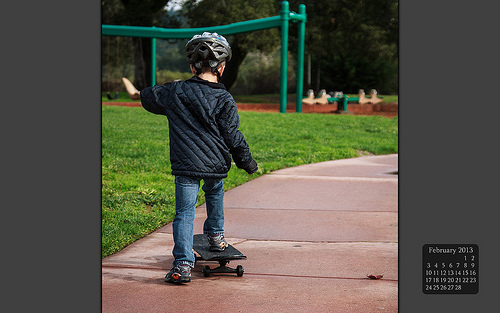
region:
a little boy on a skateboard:
[96, 18, 342, 303]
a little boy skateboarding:
[105, 5, 277, 307]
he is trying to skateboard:
[112, 28, 319, 309]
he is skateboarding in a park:
[120, 19, 303, 301]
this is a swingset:
[100, 11, 167, 120]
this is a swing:
[101, 34, 124, 102]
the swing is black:
[102, 33, 129, 113]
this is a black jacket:
[126, 63, 283, 185]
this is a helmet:
[173, 21, 249, 79]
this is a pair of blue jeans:
[162, 156, 231, 268]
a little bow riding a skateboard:
[102, 9, 282, 311]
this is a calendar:
[409, 229, 494, 303]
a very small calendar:
[412, 236, 492, 310]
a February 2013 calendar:
[412, 234, 485, 303]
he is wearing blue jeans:
[162, 164, 239, 271]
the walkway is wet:
[95, 145, 409, 311]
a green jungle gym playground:
[105, 0, 311, 115]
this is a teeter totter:
[295, 71, 392, 116]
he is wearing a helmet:
[112, 18, 296, 311]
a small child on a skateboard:
[111, 20, 278, 311]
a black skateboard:
[180, 225, 282, 297]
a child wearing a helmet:
[166, 30, 251, 101]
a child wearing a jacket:
[130, 17, 240, 187]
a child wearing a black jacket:
[130, 25, 266, 216]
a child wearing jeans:
[136, 21, 247, 266]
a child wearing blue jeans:
[132, 32, 257, 247]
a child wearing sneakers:
[140, 30, 250, 302]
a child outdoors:
[125, 25, 415, 222]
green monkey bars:
[120, 0, 317, 132]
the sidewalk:
[203, 192, 410, 305]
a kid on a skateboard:
[127, 34, 269, 292]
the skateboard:
[193, 230, 235, 281]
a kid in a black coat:
[127, 30, 255, 257]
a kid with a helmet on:
[135, 33, 258, 277]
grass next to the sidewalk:
[108, 104, 253, 182]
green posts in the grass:
[281, 4, 301, 111]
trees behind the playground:
[115, 1, 383, 86]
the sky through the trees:
[160, 0, 180, 5]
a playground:
[118, 16, 363, 108]